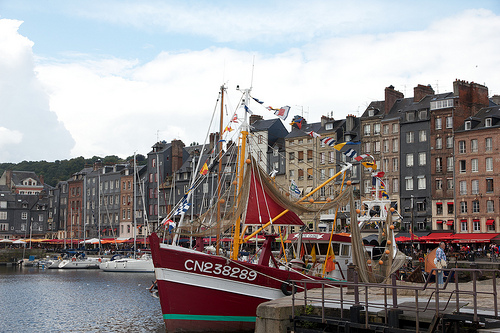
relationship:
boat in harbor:
[137, 84, 371, 329] [0, 160, 500, 331]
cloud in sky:
[6, 16, 60, 110] [0, 0, 497, 78]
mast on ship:
[153, 95, 431, 298] [142, 142, 346, 331]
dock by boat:
[313, 280, 451, 329] [143, 80, 402, 333]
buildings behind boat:
[283, 112, 343, 232] [143, 80, 402, 333]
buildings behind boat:
[356, 85, 406, 233] [143, 80, 402, 333]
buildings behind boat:
[400, 83, 450, 231] [143, 80, 402, 333]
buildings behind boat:
[433, 77, 490, 229] [143, 80, 402, 333]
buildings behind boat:
[456, 93, 498, 251] [143, 80, 402, 333]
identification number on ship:
[183, 258, 258, 281] [143, 137, 376, 331]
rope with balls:
[379, 189, 410, 283] [386, 206, 395, 261]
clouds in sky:
[5, 19, 453, 93] [54, 19, 126, 59]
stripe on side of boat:
[158, 306, 252, 331] [137, 189, 278, 315]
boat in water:
[143, 80, 402, 333] [0, 257, 170, 331]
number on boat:
[246, 269, 256, 282] [148, 84, 385, 331]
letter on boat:
[192, 258, 204, 273] [148, 84, 385, 331]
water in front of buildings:
[3, 266, 160, 331] [3, 140, 483, 217]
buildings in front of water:
[7, 121, 484, 218] [3, 274, 142, 332]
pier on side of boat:
[288, 268, 475, 321] [129, 96, 377, 328]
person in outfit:
[427, 243, 461, 288] [434, 252, 445, 276]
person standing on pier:
[427, 243, 461, 288] [271, 249, 496, 327]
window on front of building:
[417, 129, 426, 142] [396, 90, 429, 232]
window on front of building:
[405, 130, 413, 144] [396, 90, 429, 232]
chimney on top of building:
[385, 82, 397, 92] [360, 87, 495, 238]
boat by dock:
[143, 80, 402, 333] [267, 281, 484, 324]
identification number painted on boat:
[183, 258, 257, 282] [150, 76, 359, 331]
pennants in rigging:
[256, 97, 403, 189] [192, 94, 406, 273]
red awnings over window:
[431, 194, 498, 239] [434, 225, 484, 234]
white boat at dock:
[100, 148, 158, 273] [49, 236, 154, 251]